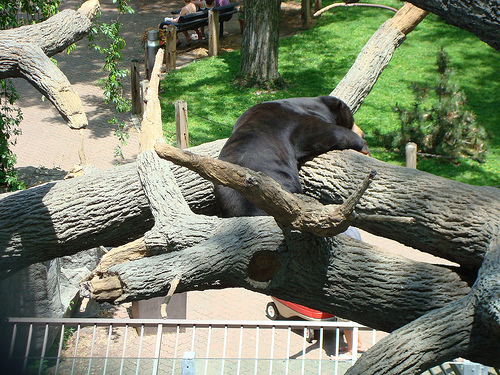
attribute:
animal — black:
[207, 92, 371, 223]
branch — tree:
[1, 130, 497, 292]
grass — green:
[290, 45, 324, 70]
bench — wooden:
[146, 9, 240, 54]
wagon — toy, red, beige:
[264, 293, 336, 341]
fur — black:
[215, 94, 345, 216]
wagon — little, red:
[262, 290, 342, 349]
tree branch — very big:
[3, 0, 106, 130]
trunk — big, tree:
[223, 4, 295, 91]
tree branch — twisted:
[325, 145, 499, 252]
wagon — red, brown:
[260, 285, 354, 342]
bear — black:
[210, 94, 370, 220]